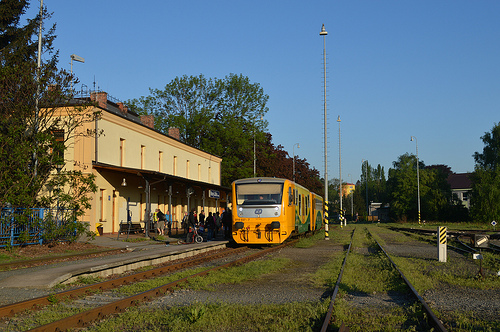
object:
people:
[199, 209, 207, 232]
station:
[23, 98, 224, 239]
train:
[228, 176, 332, 247]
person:
[182, 209, 198, 244]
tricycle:
[177, 225, 204, 245]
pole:
[320, 18, 334, 239]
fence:
[2, 204, 74, 246]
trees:
[263, 142, 326, 196]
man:
[154, 209, 169, 235]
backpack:
[160, 214, 166, 221]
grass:
[141, 304, 293, 331]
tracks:
[2, 222, 320, 329]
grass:
[353, 250, 386, 289]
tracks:
[315, 216, 450, 331]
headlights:
[237, 206, 244, 211]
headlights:
[273, 205, 279, 211]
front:
[230, 176, 286, 245]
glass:
[236, 183, 280, 203]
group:
[131, 71, 336, 231]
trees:
[131, 72, 330, 236]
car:
[227, 175, 302, 246]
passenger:
[220, 205, 233, 241]